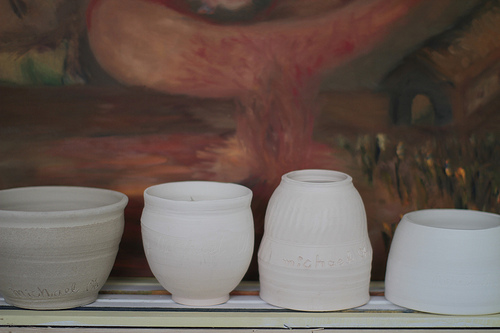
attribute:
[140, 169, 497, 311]
ceramic cups — white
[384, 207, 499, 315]
vase — ceramic, White 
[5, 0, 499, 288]
painting — multi colored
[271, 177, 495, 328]
pots — white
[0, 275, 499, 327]
top — yellow, white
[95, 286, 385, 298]
stripe — blue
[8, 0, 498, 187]
painting — brown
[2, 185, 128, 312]
vase — ceramic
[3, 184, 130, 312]
ceramic bowl — white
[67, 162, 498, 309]
pots — white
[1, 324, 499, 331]
stripe — black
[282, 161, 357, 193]
bottom — circular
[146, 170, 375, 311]
vases — ceramic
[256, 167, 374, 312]
vase — white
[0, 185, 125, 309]
beige bowl — ceramic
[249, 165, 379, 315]
cup — ceramic, upside down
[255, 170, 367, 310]
pots — white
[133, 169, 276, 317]
pot — molded, white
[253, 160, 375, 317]
vase — white, ceramic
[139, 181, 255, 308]
vase — white